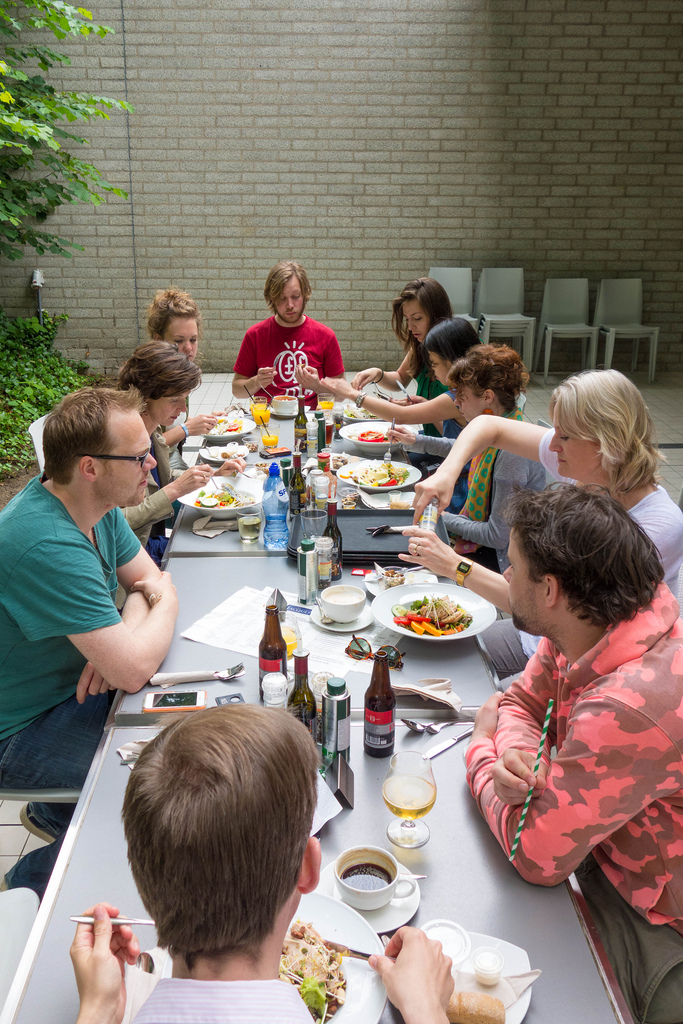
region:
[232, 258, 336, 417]
A man wearing a red shirt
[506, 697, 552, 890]
A long green drinking straw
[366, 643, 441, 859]
People are enjoying beers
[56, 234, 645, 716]
A group of people eating together.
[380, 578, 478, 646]
Various brightly colored foods are served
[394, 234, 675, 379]
There are many extra chairs in the background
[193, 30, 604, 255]
The wall is made of bricks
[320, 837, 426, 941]
Coffee is being enjoyed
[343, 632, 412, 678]
sunglasses sitting on table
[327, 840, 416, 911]
coffee cup on saucer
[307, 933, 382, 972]
butterknife in man's hand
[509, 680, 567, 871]
man holding a straw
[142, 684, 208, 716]
cell phone on table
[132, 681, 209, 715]
cell phone is white and orange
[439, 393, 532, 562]
woman's scarf is orange and green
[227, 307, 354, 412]
man wearing a shirt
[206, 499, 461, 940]
table is grey color.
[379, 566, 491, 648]
Plate is white color.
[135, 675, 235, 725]
Cell phone is in table.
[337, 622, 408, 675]
Eye glass is red and black color.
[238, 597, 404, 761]
Bottles are in table.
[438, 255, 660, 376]
Chairs are white color.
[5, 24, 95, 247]
Leaves are green color.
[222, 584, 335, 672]
Papers are in table.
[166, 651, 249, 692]
Fork is silver color.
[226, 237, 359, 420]
man wearing a red shirt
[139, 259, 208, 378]
lady to the right of man in red shirt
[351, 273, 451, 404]
a brown hair girl wearing green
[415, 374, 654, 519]
lady with her elbow up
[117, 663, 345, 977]
the back of persons head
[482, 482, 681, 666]
a man with long hair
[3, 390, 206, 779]
a man wearing glasses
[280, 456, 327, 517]
a bottle on the table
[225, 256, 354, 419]
A person with a Red shirt at the end of the table.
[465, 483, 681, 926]
A man with a peach colored cameo jacket on.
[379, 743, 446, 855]
A glass of white wine.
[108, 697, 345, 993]
The back of a blonde mans head.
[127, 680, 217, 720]
A phone with a peach case on it.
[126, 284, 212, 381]
A lady with her hair piled on top of her head.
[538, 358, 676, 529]
A lady with short wavy blonde hair.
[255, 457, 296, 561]
A bottle of water sitting on the table.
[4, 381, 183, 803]
A gentleman with a green shirt wearing glasses.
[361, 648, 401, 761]
brown beer bottle with white, grey and red label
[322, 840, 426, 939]
a white cup and saucer with coffee in it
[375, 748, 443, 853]
a wine glass with white wine in it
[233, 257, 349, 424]
a bearded man wearing a reddish tee shirt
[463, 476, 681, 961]
brown-haired man wearing a coral camo jacket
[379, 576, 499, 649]
a white plate with a veggie dish in it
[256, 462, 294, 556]
ablue plastic bottle of water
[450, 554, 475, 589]
a goldtone digital watch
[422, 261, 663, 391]
a bunch of white patio chairs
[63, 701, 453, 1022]
guy with brown hair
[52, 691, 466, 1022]
guy with brown hair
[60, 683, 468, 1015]
guy with brown hair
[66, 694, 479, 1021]
guy with brown hair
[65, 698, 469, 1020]
guy with brown hair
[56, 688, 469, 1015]
guy with brown hair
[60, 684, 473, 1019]
guy with brown hair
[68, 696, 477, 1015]
guy with brown hair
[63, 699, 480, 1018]
guy with brown hair